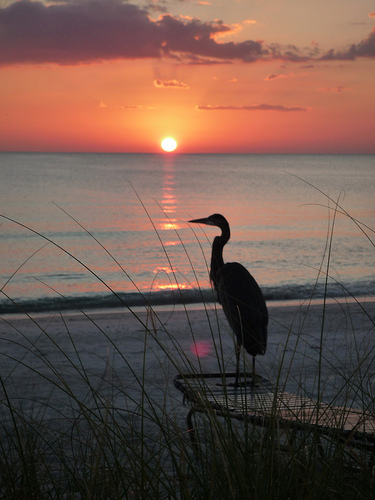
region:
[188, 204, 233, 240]
head of a bird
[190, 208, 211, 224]
peck of a bird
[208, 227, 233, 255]
neck of a bird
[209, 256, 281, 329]
body of a bird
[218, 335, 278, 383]
leg of a bird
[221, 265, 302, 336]
wing of a bird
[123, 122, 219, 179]
sunset in the background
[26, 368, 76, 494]
weed grass on a beach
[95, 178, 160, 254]
body of ocean water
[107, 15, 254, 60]
a sky full of clouds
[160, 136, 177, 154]
The sun in the sky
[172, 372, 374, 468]
A beach chair in the sand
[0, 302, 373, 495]
Sand at the beach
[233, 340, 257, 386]
The legs of the bird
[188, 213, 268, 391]
The bird is on a chair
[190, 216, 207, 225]
The beak of the bird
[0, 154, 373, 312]
A body of water near the bird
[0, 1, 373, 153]
The sky above the body of water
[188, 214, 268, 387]
The bird is standing still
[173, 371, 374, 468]
The chair is at the beach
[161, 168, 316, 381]
a bird in water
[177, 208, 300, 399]
a bird in ground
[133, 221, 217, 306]
sky in the top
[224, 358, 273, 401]
legs of the bird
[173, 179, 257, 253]
face of the bird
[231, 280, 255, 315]
skin of the bird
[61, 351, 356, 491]
a grass on the side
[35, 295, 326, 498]
a grass on the back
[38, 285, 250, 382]
a clear view of ground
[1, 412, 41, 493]
weed grass near a beach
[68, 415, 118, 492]
weed grass near a beach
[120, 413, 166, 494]
weed grass near a beach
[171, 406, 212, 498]
weed grass near a beach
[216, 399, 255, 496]
weed grass near a beach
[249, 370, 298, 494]
weed grass near a beach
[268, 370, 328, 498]
weed grass near a beach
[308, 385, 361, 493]
weed grass near a beach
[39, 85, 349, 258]
the sun is setting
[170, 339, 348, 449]
a chair is by the water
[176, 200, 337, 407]
the bird perches on the chair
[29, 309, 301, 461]
the grass is overgrown by the chair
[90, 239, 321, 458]
the sun reflects in the water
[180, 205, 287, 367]
the bird is dark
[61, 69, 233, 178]
the sky is orange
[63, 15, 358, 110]
clouds are in the sky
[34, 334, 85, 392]
the water id ark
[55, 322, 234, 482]
the grass is tall